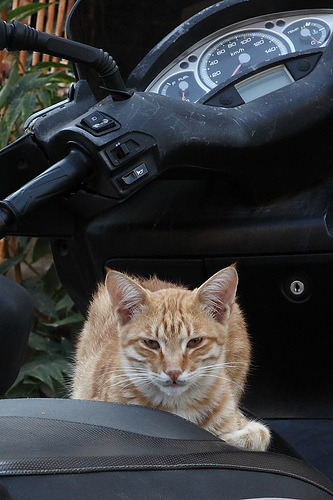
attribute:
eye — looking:
[138, 338, 162, 354]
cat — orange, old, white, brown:
[75, 271, 303, 454]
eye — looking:
[184, 334, 204, 351]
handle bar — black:
[0, 37, 332, 234]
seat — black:
[6, 393, 283, 478]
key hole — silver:
[282, 278, 310, 299]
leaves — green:
[1, 55, 72, 123]